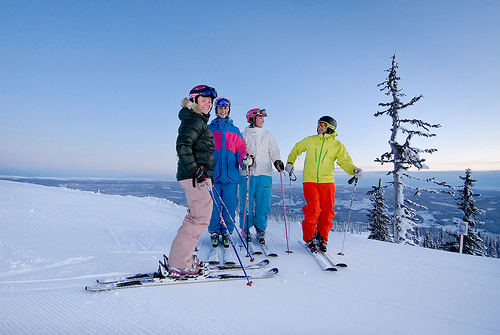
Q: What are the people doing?
A: Skiing.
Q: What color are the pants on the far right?
A: Orange.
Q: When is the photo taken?
A: Daytime.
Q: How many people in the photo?
A: Four.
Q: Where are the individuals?
A: Ski slope.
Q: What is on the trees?
A: Snow.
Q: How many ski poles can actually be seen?
A: Seven.